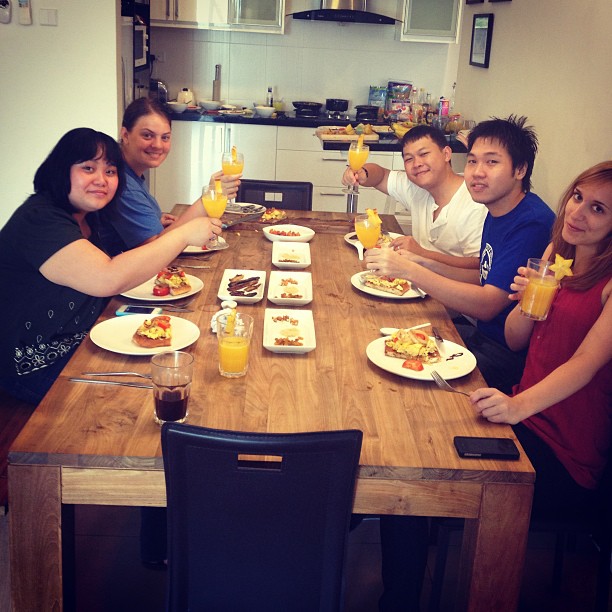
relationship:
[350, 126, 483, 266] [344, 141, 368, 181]
man holding up h glass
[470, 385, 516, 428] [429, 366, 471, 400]
hand holding fork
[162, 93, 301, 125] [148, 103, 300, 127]
plates/bowls on counter